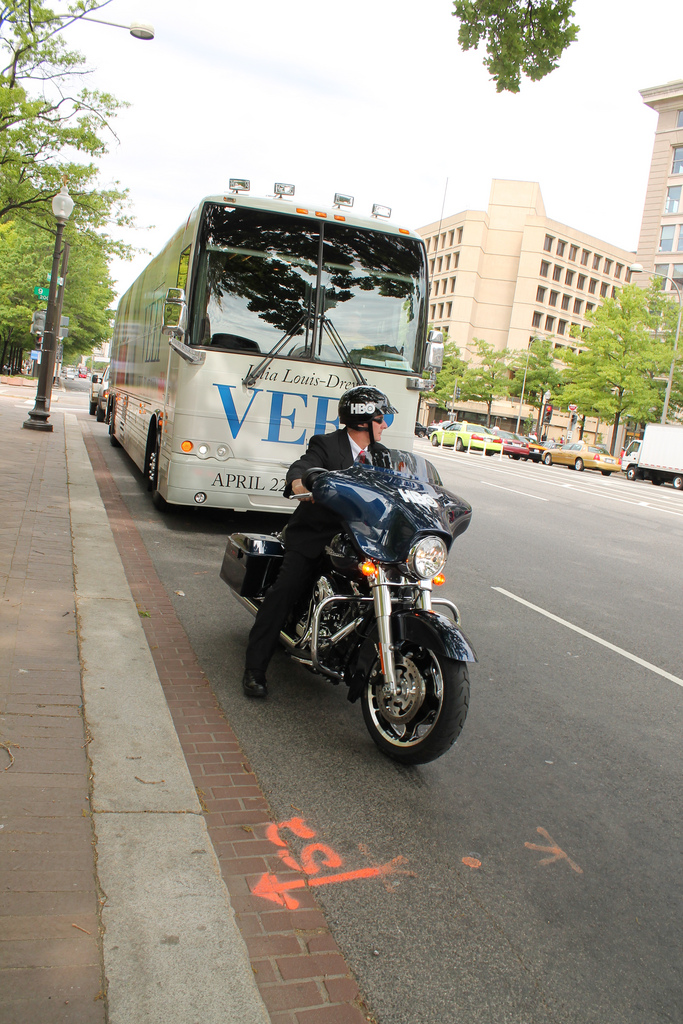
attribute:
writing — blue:
[163, 357, 492, 460]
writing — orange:
[234, 751, 610, 925]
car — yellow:
[437, 405, 497, 450]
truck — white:
[623, 411, 682, 500]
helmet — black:
[339, 383, 388, 423]